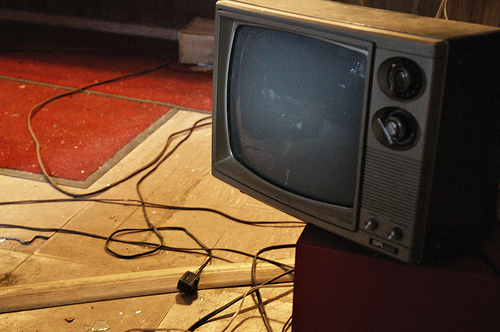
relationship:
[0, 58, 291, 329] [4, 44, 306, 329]
brown cord on floor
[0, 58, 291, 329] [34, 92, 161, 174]
brown cord on red rug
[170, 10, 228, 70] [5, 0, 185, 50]
box on shelf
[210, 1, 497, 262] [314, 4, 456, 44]
television has dust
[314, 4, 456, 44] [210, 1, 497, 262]
dust on television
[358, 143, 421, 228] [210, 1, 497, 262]
speaker on television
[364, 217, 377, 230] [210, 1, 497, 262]
dial in television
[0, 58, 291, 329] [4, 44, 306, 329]
brown cord all over floor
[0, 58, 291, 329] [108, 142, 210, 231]
brown cord on floor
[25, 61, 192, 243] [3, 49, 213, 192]
brown cord on carpet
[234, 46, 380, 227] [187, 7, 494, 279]
monitor of tv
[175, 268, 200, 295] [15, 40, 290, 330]
plug to cord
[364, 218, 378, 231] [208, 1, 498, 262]
dial on television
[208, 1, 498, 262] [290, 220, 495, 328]
television on table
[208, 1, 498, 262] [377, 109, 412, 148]
television with knobs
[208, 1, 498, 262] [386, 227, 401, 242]
television with dials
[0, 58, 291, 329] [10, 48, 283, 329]
brown cord on floor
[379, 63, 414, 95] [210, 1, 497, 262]
knob on television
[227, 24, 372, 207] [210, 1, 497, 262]
monitor on television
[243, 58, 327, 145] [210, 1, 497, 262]
reflection on television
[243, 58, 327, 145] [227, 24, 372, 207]
reflection on monitor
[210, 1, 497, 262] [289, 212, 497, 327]
television on stand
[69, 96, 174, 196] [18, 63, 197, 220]
trim on rug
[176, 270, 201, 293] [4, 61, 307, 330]
plug of cord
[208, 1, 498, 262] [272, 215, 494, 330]
television on table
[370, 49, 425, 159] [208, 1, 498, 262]
knobs on television